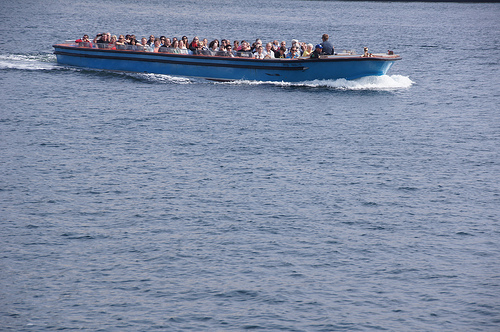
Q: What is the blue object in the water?
A: Speed Boat.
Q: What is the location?
A: Water.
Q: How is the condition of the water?
A: Calm.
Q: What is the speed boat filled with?
A: Many people.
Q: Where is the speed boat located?
A: Water.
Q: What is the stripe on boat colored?
A: Black.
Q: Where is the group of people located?
A: Boat.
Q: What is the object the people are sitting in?
A: Boat.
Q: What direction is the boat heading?
A: Right.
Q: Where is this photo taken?
A: On the water.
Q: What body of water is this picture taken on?
A: OCean.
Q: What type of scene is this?
A: Outdoor.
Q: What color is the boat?
A: Blue.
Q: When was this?
A: Daytime.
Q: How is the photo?
A: Clear.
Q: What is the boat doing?
A: Moving.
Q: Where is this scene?
A: Waterbody.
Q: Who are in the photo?
A: People.